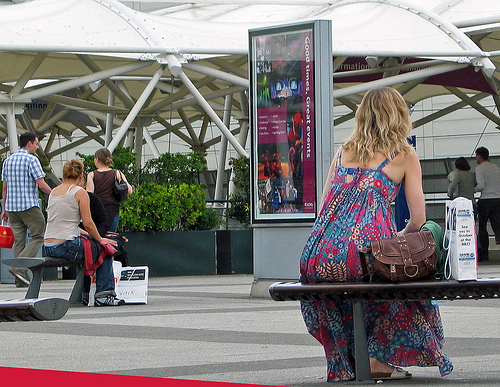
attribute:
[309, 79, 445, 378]
woman — resting, sitting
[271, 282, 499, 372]
bench — metal, dark grey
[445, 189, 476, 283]
bag — white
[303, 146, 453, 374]
dress — floral, blue, red, peach, long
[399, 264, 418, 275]
buckle — metal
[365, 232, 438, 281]
purse — leather, brown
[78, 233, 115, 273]
strap — red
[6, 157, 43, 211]
shirt — blue, checked, plaid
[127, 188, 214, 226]
shrub — green, growing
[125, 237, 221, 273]
planter — black, green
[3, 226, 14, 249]
bag — red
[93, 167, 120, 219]
tank top — brown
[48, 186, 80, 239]
tank top — white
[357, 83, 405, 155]
hair — blonde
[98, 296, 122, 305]
shoes — black, blue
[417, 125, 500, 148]
wall — grey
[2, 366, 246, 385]
line — red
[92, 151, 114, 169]
hair — brown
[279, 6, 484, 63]
pipe — white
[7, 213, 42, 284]
pants — khaki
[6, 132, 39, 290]
man — walking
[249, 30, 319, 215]
sign — encased